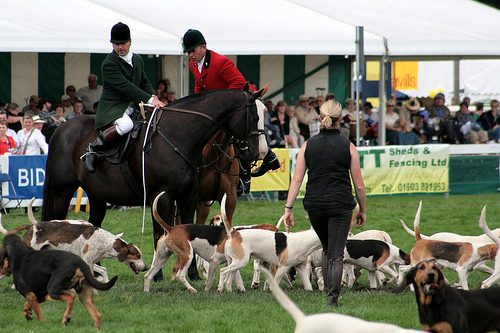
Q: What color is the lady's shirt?
A: Black.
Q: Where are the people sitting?
A: Under tent.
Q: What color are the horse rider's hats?
A: Black.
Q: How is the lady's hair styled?
A: Ponytail.